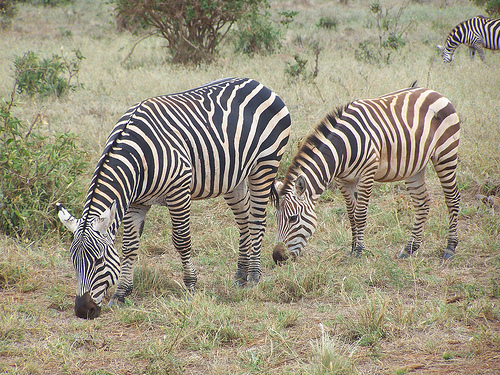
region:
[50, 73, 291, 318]
a zebra graising in a field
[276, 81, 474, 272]
young zebra eating grass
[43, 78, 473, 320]
two animals standing in a field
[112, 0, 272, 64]
a small bush in a prarie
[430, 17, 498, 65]
a distant zebra obscured by grass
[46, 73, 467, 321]
two mammals in a savannah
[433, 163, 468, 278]
leg of a zebra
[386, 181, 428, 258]
leg of a zebra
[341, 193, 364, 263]
legs of zebra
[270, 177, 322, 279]
face of a zebra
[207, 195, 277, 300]
legs of a zebra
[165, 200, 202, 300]
leg of a zebra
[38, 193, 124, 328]
face of a zebra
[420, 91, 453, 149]
stripes on a zebra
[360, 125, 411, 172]
stripes on a zebra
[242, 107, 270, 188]
stripes on a zebra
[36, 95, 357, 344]
a zebra standing outside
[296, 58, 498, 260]
a zebra standing outside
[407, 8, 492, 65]
a zebra standign outside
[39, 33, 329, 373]
a zebra eating grass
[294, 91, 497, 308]
a zebra eating grass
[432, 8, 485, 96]
a zebra eating grass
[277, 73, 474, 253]
a black and white zebra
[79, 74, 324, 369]
black and white zebra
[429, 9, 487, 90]
black and white zebra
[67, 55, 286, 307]
zebra standing otuside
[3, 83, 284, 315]
white and black striped zebra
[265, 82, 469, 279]
white and black striped zebra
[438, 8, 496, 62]
white and black striped zebra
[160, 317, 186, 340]
long green and yellow grass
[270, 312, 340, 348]
long green and yellow grass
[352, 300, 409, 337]
long green and yellow grass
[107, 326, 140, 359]
long green and yellow grass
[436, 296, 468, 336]
long green and yellow grass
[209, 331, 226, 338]
long green and yellow grass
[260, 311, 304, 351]
long green and yellow grass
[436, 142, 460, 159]
black stripe on zebra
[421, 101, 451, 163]
black stripe on zebra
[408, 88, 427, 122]
black stripe on zebra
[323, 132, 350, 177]
black stripe on zebra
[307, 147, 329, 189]
black stripe on zebra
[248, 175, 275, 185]
black stripe on zebra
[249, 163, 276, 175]
black stripe on zebra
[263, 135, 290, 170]
black stripe on zebra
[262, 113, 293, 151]
black stripe on zebra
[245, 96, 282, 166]
black stripe on zebra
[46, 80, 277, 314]
black and white striped zebra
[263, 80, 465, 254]
black and white striped zebra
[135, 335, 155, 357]
long green and yellow grass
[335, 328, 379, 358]
long green and yellow grass